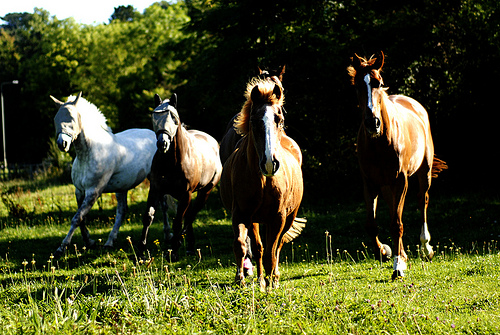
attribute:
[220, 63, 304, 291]
horse — brown, first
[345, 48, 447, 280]
horse — brown, second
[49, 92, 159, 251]
horse — white, running, third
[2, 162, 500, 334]
grass — long, green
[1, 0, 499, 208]
trees — leafy, green, leafy green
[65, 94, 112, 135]
mane — white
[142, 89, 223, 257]
horse — brown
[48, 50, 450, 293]
horses — a herd, exercising, running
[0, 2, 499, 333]
field — grassy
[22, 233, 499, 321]
flowers — wild, tall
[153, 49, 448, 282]
horses — running, brown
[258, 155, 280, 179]
nose — white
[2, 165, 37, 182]
fence — white